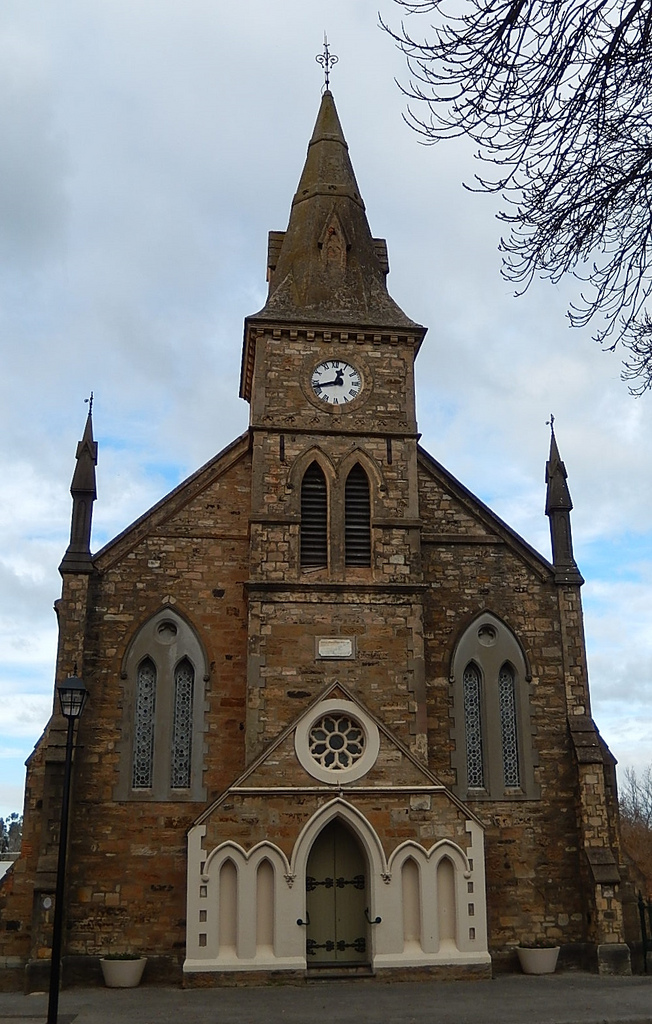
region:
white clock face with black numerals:
[308, 358, 361, 405]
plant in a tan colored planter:
[95, 950, 147, 989]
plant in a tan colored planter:
[514, 938, 564, 977]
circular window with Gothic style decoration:
[294, 696, 384, 784]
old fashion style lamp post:
[43, 660, 87, 1021]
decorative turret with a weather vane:
[541, 412, 584, 587]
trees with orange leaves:
[618, 764, 651, 975]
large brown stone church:
[0, 28, 651, 992]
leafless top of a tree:
[378, 0, 650, 401]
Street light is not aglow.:
[49, 665, 84, 1019]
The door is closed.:
[290, 794, 384, 983]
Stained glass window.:
[446, 605, 536, 806]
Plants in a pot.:
[96, 944, 142, 982]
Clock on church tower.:
[305, 352, 369, 412]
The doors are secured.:
[292, 785, 383, 981]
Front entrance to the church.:
[283, 791, 381, 984]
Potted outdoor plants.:
[517, 935, 560, 972]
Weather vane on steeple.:
[314, 30, 338, 90]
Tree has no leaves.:
[377, 0, 648, 363]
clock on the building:
[301, 352, 374, 415]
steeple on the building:
[234, 23, 426, 372]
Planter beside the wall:
[509, 931, 566, 977]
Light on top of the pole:
[49, 667, 94, 718]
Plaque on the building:
[309, 625, 360, 669]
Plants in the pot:
[99, 949, 145, 963]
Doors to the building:
[295, 815, 371, 973]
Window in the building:
[434, 598, 536, 799]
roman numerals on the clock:
[304, 354, 364, 408]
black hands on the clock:
[313, 368, 351, 388]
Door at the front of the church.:
[303, 813, 371, 966]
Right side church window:
[451, 606, 537, 801]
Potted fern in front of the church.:
[99, 948, 147, 988]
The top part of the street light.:
[59, 676, 86, 716]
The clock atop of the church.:
[304, 351, 371, 406]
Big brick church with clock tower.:
[1, 32, 632, 974]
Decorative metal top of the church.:
[314, 28, 339, 91]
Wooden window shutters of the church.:
[291, 451, 380, 566]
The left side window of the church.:
[121, 606, 207, 799]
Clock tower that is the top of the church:
[243, 34, 428, 681]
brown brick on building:
[255, 523, 283, 546]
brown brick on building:
[142, 542, 172, 572]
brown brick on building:
[186, 548, 229, 609]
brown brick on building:
[96, 605, 133, 632]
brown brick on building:
[93, 721, 120, 771]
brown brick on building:
[85, 804, 122, 845]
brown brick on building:
[122, 841, 193, 907]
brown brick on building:
[436, 573, 475, 592]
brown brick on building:
[501, 579, 537, 618]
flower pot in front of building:
[514, 934, 563, 971]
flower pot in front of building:
[96, 943, 149, 984]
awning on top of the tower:
[305, 33, 345, 86]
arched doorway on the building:
[293, 800, 382, 978]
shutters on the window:
[343, 460, 371, 570]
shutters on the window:
[295, 456, 329, 568]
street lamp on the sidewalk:
[26, 660, 97, 1022]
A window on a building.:
[131, 661, 156, 790]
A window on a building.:
[463, 651, 487, 798]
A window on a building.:
[493, 656, 519, 781]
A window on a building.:
[338, 457, 389, 579]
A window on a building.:
[293, 449, 338, 578]